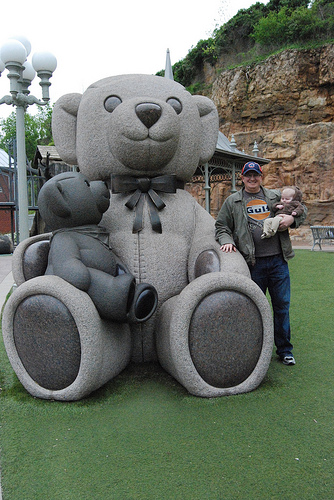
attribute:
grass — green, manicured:
[11, 407, 333, 495]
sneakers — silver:
[276, 350, 300, 365]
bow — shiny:
[238, 187, 276, 208]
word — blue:
[242, 204, 270, 215]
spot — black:
[317, 79, 332, 97]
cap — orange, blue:
[238, 158, 266, 179]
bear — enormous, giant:
[3, 63, 282, 413]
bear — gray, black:
[22, 162, 161, 322]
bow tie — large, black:
[95, 164, 191, 239]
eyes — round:
[97, 92, 191, 120]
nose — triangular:
[136, 96, 166, 137]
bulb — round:
[26, 45, 64, 78]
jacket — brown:
[212, 182, 299, 263]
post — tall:
[6, 46, 58, 253]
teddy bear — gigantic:
[2, 55, 285, 411]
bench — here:
[304, 217, 332, 256]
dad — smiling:
[205, 159, 323, 377]